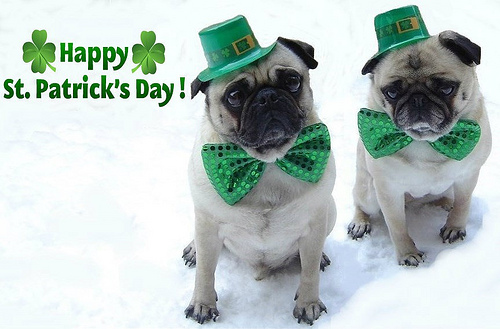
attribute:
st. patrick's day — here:
[1, 69, 197, 114]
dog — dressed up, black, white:
[173, 9, 340, 328]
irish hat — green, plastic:
[180, 9, 288, 92]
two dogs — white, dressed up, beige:
[169, 1, 498, 324]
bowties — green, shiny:
[192, 101, 485, 211]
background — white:
[2, 107, 173, 326]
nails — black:
[174, 306, 341, 327]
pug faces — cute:
[212, 67, 470, 169]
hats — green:
[188, 0, 435, 89]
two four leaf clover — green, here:
[17, 22, 174, 78]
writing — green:
[1, 24, 215, 122]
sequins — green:
[364, 114, 392, 145]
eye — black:
[275, 69, 306, 93]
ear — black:
[276, 33, 326, 75]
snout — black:
[235, 81, 294, 114]